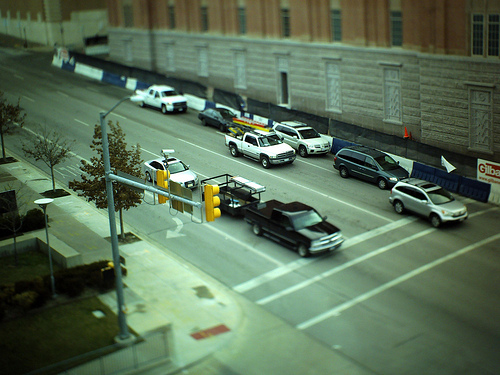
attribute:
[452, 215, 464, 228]
suv — silver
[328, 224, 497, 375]
road — paved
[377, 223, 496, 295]
road — paved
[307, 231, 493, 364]
road — paved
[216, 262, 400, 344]
road — paved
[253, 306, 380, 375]
road — paved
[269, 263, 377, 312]
road — paved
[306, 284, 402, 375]
road — paved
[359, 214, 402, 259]
road — paved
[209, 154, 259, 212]
cart — black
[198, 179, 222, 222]
light — traffic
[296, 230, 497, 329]
line — white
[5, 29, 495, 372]
street — city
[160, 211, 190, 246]
arrow — white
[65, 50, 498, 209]
barriers — blue, white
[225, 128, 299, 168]
truck — white, pickup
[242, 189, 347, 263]
truck — black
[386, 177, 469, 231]
suv — silver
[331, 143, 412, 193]
car — black, minivan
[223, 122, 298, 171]
truck — white, pickup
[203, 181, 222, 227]
lights — traffic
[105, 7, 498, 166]
building — multi story, brick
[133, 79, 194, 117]
truck — white, pickup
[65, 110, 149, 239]
trees — tall, green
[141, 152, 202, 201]
car — silver